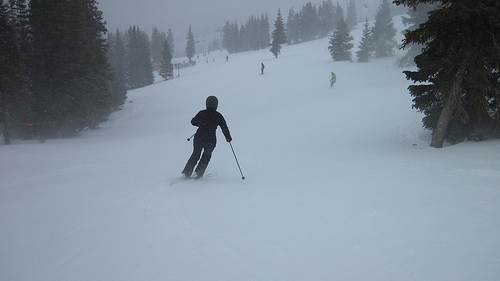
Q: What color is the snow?
A: White.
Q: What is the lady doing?
A: Skiing.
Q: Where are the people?
A: In the snow.